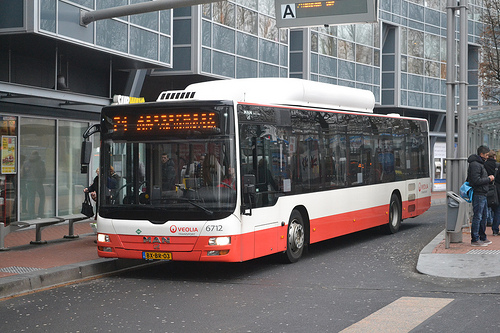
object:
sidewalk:
[450, 252, 496, 289]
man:
[466, 145, 495, 247]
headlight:
[208, 236, 231, 245]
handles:
[82, 189, 92, 203]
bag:
[457, 182, 474, 204]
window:
[388, 121, 430, 182]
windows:
[238, 106, 291, 199]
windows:
[312, 114, 392, 190]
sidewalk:
[416, 219, 500, 279]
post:
[442, 0, 469, 250]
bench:
[8, 209, 89, 245]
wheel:
[387, 189, 403, 233]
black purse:
[80, 191, 95, 218]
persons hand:
[83, 188, 89, 193]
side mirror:
[80, 139, 94, 174]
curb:
[0, 258, 154, 292]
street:
[0, 201, 500, 331]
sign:
[0, 134, 16, 175]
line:
[334, 296, 455, 333]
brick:
[41, 246, 68, 261]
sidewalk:
[0, 217, 100, 274]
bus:
[90, 76, 435, 265]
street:
[83, 233, 428, 326]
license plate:
[142, 251, 173, 260]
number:
[205, 224, 223, 232]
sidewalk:
[431, 187, 446, 204]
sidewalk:
[378, 225, 499, 333]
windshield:
[96, 105, 234, 216]